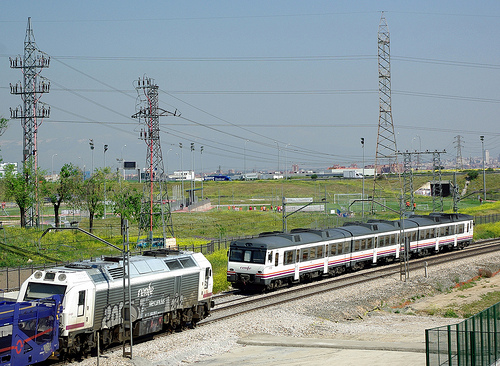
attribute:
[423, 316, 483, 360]
fence — black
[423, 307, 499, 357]
fence — black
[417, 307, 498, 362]
fence — black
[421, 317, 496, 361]
fence — black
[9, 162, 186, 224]
trees — green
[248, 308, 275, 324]
gravel — gray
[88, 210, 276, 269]
grass — green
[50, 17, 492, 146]
sky — blue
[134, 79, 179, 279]
pole — metal, utility pole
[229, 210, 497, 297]
train — passenger train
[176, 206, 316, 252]
grass — green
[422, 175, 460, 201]
entrance — tunnel entrance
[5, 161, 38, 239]
tree — growing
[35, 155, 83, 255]
tree — growing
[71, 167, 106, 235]
tree — growing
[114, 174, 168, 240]
tree — growing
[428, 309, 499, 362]
fence — green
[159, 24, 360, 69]
sky — Blue 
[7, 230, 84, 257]
fence — background, Green 